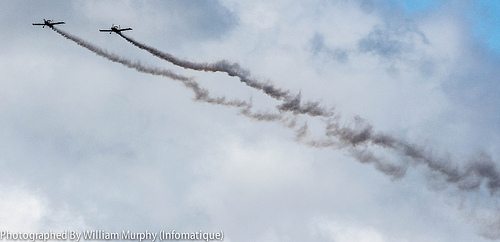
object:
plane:
[98, 24, 133, 36]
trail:
[127, 34, 235, 64]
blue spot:
[400, 0, 500, 43]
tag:
[0, 229, 227, 242]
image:
[0, 0, 497, 242]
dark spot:
[0, 0, 55, 23]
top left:
[0, 0, 175, 110]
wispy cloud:
[356, 8, 428, 81]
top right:
[321, 0, 498, 118]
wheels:
[109, 33, 112, 34]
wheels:
[43, 26, 45, 28]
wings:
[121, 27, 135, 31]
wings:
[52, 21, 67, 25]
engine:
[114, 26, 118, 28]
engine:
[44, 19, 48, 21]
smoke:
[102, 40, 270, 108]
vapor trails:
[209, 59, 262, 77]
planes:
[31, 18, 66, 29]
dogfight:
[29, 18, 134, 35]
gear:
[48, 25, 55, 28]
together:
[31, 18, 134, 35]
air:
[0, 0, 499, 242]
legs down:
[109, 32, 112, 35]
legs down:
[43, 26, 46, 29]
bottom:
[0, 201, 499, 242]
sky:
[0, 0, 500, 242]